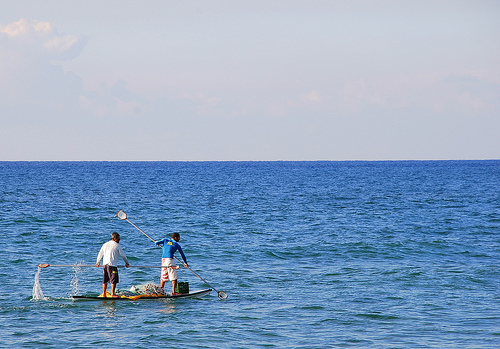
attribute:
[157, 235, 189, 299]
man — skinny, paddling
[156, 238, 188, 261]
shirt — blue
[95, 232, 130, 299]
man — skinny, paddling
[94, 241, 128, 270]
shirt — white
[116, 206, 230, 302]
paddle — long, white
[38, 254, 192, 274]
paddle — long, white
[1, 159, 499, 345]
ocean — blue, still, vast, calm, bluish-green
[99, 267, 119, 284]
shorts — black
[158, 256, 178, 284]
shorts — patterned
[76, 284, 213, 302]
surfboard — long, wide